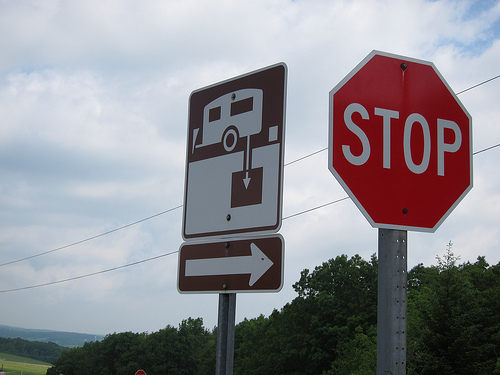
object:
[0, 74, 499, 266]
powerlines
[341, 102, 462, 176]
stop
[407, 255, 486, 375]
tree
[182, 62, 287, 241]
sign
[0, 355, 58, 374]
ground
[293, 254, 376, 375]
trees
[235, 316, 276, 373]
trees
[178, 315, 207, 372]
trees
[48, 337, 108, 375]
trees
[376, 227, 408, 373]
metal post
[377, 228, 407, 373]
pole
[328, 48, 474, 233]
stop sign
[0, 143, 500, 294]
wires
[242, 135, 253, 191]
arrow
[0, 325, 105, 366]
mountains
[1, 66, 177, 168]
cloud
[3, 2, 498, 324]
sky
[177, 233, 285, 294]
sign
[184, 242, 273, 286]
arrow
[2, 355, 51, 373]
field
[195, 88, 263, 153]
camper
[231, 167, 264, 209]
septic tank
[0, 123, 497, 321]
distance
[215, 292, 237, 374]
pole